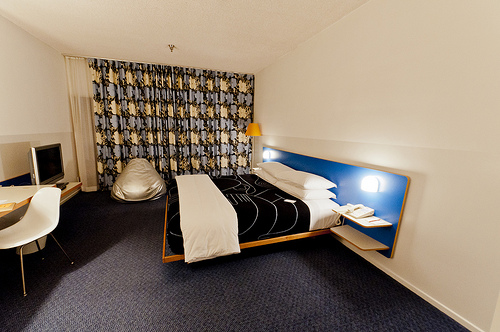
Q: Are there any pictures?
A: No, there are no pictures.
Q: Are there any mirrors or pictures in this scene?
A: No, there are no pictures or mirrors.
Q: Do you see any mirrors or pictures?
A: No, there are no pictures or mirrors.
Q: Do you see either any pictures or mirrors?
A: No, there are no pictures or mirrors.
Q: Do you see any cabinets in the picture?
A: No, there are no cabinets.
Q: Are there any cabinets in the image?
A: No, there are no cabinets.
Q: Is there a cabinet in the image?
A: No, there are no cabinets.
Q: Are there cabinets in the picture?
A: No, there are no cabinets.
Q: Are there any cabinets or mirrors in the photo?
A: No, there are no cabinets or mirrors.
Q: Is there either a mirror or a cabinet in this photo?
A: No, there are no cabinets or mirrors.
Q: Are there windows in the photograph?
A: Yes, there is a window.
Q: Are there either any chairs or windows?
A: Yes, there is a window.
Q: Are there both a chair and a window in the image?
A: Yes, there are both a window and a chair.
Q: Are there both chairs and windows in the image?
A: Yes, there are both a window and a chair.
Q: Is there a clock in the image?
A: No, there are no clocks.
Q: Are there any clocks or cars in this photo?
A: No, there are no clocks or cars.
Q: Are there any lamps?
A: Yes, there is a lamp.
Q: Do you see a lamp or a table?
A: Yes, there is a lamp.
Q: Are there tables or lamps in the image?
A: Yes, there is a lamp.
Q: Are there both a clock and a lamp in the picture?
A: No, there is a lamp but no clocks.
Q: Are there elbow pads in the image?
A: No, there are no elbow pads.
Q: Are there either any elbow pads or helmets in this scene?
A: No, there are no elbow pads or helmets.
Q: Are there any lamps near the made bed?
A: Yes, there is a lamp near the bed.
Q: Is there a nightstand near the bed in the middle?
A: No, there is a lamp near the bed.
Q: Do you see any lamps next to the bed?
A: Yes, there is a lamp next to the bed.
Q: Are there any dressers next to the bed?
A: No, there is a lamp next to the bed.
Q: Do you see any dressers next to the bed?
A: No, there is a lamp next to the bed.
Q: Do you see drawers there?
A: No, there are no drawers.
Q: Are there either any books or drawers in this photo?
A: No, there are no drawers or books.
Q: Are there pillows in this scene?
A: Yes, there are pillows.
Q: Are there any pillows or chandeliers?
A: Yes, there are pillows.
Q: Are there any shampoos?
A: No, there are no shampoos.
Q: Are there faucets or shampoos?
A: No, there are no shampoos or faucets.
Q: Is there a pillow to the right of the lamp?
A: Yes, there are pillows to the right of the lamp.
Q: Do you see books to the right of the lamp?
A: No, there are pillows to the right of the lamp.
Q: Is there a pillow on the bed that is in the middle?
A: Yes, there are pillows on the bed.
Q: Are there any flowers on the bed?
A: No, there are pillows on the bed.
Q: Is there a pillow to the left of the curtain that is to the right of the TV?
A: No, the pillows are to the right of the curtain.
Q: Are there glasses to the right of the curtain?
A: No, there are pillows to the right of the curtain.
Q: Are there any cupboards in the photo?
A: No, there are no cupboards.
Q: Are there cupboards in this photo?
A: No, there are no cupboards.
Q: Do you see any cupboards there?
A: No, there are no cupboards.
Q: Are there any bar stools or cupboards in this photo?
A: No, there are no cupboards or bar stools.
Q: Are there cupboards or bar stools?
A: No, there are no cupboards or bar stools.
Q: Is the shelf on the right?
A: Yes, the shelf is on the right of the image.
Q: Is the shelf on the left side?
A: No, the shelf is on the right of the image.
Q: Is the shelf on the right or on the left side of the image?
A: The shelf is on the right of the image.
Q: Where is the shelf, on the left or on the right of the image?
A: The shelf is on the right of the image.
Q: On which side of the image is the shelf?
A: The shelf is on the right of the image.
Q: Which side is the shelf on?
A: The shelf is on the right of the image.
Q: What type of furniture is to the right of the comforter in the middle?
A: The piece of furniture is a shelf.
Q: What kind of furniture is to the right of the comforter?
A: The piece of furniture is a shelf.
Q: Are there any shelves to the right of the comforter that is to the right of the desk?
A: Yes, there is a shelf to the right of the comforter.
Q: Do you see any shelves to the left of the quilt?
A: No, the shelf is to the right of the quilt.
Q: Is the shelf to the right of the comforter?
A: Yes, the shelf is to the right of the comforter.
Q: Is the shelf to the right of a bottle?
A: No, the shelf is to the right of the comforter.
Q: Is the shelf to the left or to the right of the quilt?
A: The shelf is to the right of the quilt.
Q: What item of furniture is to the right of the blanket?
A: The piece of furniture is a shelf.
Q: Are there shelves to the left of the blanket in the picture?
A: No, the shelf is to the right of the blanket.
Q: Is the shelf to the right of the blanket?
A: Yes, the shelf is to the right of the blanket.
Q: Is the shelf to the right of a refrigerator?
A: No, the shelf is to the right of the blanket.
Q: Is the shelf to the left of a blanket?
A: No, the shelf is to the right of a blanket.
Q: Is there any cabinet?
A: No, there are no cabinets.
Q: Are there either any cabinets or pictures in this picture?
A: No, there are no cabinets or pictures.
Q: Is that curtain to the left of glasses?
A: No, the curtain is to the left of the pillows.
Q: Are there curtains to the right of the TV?
A: Yes, there is a curtain to the right of the TV.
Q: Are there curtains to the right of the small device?
A: Yes, there is a curtain to the right of the TV.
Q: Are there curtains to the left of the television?
A: No, the curtain is to the right of the television.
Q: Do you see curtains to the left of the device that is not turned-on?
A: No, the curtain is to the right of the television.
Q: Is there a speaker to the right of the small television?
A: No, there is a curtain to the right of the TV.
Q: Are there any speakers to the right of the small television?
A: No, there is a curtain to the right of the TV.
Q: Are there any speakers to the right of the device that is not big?
A: No, there is a curtain to the right of the TV.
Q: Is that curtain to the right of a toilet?
A: No, the curtain is to the right of a television.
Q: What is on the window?
A: The curtain is on the window.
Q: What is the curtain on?
A: The curtain is on the window.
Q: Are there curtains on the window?
A: Yes, there is a curtain on the window.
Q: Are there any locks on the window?
A: No, there is a curtain on the window.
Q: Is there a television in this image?
A: Yes, there is a television.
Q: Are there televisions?
A: Yes, there is a television.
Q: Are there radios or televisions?
A: Yes, there is a television.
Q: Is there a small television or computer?
A: Yes, there is a small television.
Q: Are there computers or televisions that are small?
A: Yes, the television is small.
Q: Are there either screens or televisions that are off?
A: Yes, the television is off.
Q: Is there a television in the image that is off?
A: Yes, there is a television that is off.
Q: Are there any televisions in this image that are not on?
A: Yes, there is a television that is off.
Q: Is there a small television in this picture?
A: Yes, there is a small television.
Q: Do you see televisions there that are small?
A: Yes, there is a small television.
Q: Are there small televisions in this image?
A: Yes, there is a small television.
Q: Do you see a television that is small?
A: Yes, there is a small television.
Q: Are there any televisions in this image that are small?
A: Yes, there is a television that is small.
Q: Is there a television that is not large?
A: Yes, there is a small television.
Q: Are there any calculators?
A: No, there are no calculators.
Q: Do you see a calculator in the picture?
A: No, there are no calculators.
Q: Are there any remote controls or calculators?
A: No, there are no calculators or remote controls.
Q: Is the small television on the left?
A: Yes, the television is on the left of the image.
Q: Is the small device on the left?
A: Yes, the television is on the left of the image.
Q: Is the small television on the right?
A: No, the TV is on the left of the image.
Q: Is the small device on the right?
A: No, the TV is on the left of the image.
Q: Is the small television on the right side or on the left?
A: The TV is on the left of the image.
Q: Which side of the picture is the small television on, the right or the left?
A: The TV is on the left of the image.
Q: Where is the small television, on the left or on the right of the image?
A: The TV is on the left of the image.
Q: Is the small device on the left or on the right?
A: The TV is on the left of the image.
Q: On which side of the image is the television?
A: The television is on the left of the image.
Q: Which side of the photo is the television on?
A: The television is on the left of the image.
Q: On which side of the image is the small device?
A: The television is on the left of the image.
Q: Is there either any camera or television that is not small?
A: No, there is a television but it is small.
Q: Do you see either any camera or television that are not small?
A: No, there is a television but it is small.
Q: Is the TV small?
A: Yes, the TV is small.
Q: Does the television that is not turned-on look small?
A: Yes, the TV is small.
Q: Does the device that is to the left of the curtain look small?
A: Yes, the TV is small.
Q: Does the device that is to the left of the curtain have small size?
A: Yes, the TV is small.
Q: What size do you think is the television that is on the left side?
A: The TV is small.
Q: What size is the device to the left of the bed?
A: The TV is small.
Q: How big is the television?
A: The television is small.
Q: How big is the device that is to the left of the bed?
A: The television is small.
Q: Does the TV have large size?
A: No, the TV is small.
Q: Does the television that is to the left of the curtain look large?
A: No, the television is small.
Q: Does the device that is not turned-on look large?
A: No, the television is small.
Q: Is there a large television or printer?
A: No, there is a television but it is small.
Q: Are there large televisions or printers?
A: No, there is a television but it is small.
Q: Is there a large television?
A: No, there is a television but it is small.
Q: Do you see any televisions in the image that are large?
A: No, there is a television but it is small.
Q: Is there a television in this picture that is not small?
A: No, there is a television but it is small.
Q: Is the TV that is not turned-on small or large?
A: The TV is small.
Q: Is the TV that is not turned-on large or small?
A: The TV is small.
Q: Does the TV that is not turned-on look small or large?
A: The TV is small.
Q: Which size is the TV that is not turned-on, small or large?
A: The TV is small.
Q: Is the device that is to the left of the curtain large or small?
A: The TV is small.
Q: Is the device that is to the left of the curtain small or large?
A: The TV is small.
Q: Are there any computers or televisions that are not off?
A: No, there is a television but it is off.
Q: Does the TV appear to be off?
A: Yes, the TV is off.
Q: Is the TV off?
A: Yes, the TV is off.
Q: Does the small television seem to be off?
A: Yes, the TV is off.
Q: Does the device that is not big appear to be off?
A: Yes, the TV is off.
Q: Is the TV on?
A: No, the TV is off.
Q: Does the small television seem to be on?
A: No, the television is off.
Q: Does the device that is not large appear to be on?
A: No, the television is off.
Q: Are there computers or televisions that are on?
A: No, there is a television but it is off.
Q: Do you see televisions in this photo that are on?
A: No, there is a television but it is off.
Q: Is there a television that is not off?
A: No, there is a television but it is off.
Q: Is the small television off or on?
A: The television is off.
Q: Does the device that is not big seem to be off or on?
A: The television is off.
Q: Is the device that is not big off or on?
A: The television is off.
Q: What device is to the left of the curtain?
A: The device is a television.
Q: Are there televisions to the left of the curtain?
A: Yes, there is a television to the left of the curtain.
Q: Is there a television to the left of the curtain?
A: Yes, there is a television to the left of the curtain.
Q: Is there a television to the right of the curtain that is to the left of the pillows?
A: No, the television is to the left of the curtain.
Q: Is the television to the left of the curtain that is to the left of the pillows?
A: Yes, the television is to the left of the curtain.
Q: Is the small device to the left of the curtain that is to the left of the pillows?
A: Yes, the television is to the left of the curtain.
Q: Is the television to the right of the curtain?
A: No, the television is to the left of the curtain.